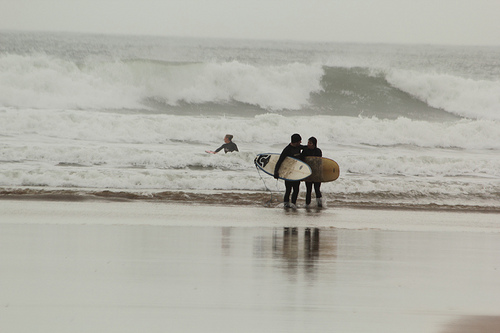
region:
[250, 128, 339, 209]
two surfers leaving the ocean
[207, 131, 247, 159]
surfer paddling in the ocean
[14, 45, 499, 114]
wave breaking in the ocean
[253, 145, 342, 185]
two surferboards being carried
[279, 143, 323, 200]
black wetsuits of surfers walking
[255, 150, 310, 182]
white and black surfboard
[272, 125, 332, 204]
surfer walking with his arm around other surfer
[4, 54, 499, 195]
white foam from the waves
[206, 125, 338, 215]
three people in the ocean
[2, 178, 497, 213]
water meeting shoreline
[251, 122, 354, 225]
two people standing on a beach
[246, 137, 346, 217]
two people holding surf boards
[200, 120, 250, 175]
a person in the ocean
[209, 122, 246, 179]
a person swimming in the ocean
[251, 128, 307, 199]
a man holding a white surf board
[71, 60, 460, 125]
a big wave in the ocean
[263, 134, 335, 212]
two people wearing wet suits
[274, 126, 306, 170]
a person wearing a hat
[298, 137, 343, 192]
a person holding a yellow surf board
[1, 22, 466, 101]
a large body of water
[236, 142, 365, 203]
these people are holding surf boards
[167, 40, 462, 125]
this is an ocean wave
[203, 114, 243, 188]
a surfer that is in the water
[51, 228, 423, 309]
this area is covered in sand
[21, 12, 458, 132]
this is the ocean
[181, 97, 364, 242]
there are a total of three people in this area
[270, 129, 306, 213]
the color of the mans wet suit is black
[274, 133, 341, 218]
the people are wearing wet suits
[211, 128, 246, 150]
the woman's hair is pulled back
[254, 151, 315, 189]
the mans surf board is white with a black design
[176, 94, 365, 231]
three surfers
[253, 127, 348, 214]
two surfers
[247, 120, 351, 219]
surfers carrying their surfboards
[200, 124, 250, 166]
a surfer in the water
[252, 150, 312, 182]
a surfboard the surfer is carrying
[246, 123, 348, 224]
two surfers wearing wetsuits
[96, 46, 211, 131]
a high wave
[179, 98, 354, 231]
surfers in the beach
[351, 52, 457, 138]
a wave in the ocean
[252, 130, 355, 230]
two surfers walking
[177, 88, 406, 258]
a group of surfers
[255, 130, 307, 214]
a person holding a white surfboard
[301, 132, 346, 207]
a person holding a yellow surfboard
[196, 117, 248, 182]
an surfer out in the water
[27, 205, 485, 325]
a flat stretch of wet sand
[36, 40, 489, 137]
a wave beginning to crash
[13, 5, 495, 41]
a cloudy gray sky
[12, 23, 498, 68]
the edge of the horizon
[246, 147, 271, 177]
a black logo on the back of a surfboard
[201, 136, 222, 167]
the edge of a red surfboard